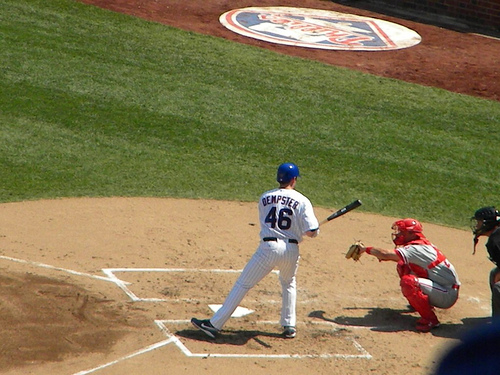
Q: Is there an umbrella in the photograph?
A: No, there are no umbrellas.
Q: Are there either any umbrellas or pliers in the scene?
A: No, there are no umbrellas or pliers.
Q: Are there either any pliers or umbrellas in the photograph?
A: No, there are no umbrellas or pliers.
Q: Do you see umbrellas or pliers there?
A: No, there are no umbrellas or pliers.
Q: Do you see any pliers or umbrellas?
A: No, there are no umbrellas or pliers.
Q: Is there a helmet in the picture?
A: Yes, there is a helmet.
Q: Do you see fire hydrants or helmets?
A: Yes, there is a helmet.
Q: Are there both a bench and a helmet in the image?
A: No, there is a helmet but no benches.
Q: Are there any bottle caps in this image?
A: No, there are no bottle caps.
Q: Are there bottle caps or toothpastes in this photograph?
A: No, there are no bottle caps or toothpastes.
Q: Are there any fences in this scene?
A: No, there are no fences.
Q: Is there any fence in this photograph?
A: No, there are no fences.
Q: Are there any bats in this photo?
A: Yes, there is a bat.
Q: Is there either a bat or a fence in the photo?
A: Yes, there is a bat.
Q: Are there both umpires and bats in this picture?
A: Yes, there are both a bat and an umpire.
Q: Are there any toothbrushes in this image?
A: No, there are no toothbrushes.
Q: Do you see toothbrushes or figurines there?
A: No, there are no toothbrushes or figurines.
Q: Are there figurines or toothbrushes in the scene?
A: No, there are no toothbrushes or figurines.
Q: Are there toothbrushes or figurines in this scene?
A: No, there are no toothbrushes or figurines.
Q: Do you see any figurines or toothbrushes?
A: No, there are no toothbrushes or figurines.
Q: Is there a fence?
A: No, there are no fences.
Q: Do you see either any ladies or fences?
A: No, there are no fences or ladies.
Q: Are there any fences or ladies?
A: No, there are no fences or ladies.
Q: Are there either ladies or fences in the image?
A: No, there are no fences or ladies.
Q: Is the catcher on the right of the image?
A: Yes, the catcher is on the right of the image.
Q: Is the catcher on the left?
A: No, the catcher is on the right of the image.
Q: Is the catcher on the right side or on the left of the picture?
A: The catcher is on the right of the image.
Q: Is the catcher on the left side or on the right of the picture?
A: The catcher is on the right of the image.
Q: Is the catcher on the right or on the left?
A: The catcher is on the right of the image.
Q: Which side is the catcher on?
A: The catcher is on the right of the image.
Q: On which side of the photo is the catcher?
A: The catcher is on the right of the image.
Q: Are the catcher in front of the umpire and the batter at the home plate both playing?
A: Yes, both the catcher and the batter are playing.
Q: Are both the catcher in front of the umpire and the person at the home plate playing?
A: Yes, both the catcher and the batter are playing.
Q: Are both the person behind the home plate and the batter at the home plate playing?
A: Yes, both the catcher and the batter are playing.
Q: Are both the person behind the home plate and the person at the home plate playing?
A: Yes, both the catcher and the batter are playing.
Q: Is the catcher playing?
A: Yes, the catcher is playing.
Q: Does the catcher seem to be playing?
A: Yes, the catcher is playing.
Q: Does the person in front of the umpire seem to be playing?
A: Yes, the catcher is playing.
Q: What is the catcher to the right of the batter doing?
A: The catcher is playing.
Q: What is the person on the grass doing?
A: The catcher is playing.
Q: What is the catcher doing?
A: The catcher is playing.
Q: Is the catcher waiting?
A: No, the catcher is playing.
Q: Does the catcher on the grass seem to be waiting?
A: No, the catcher is playing.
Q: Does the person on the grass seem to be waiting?
A: No, the catcher is playing.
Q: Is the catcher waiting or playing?
A: The catcher is playing.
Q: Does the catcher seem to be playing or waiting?
A: The catcher is playing.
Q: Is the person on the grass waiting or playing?
A: The catcher is playing.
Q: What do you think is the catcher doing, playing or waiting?
A: The catcher is playing.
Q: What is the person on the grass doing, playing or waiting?
A: The catcher is playing.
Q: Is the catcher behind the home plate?
A: Yes, the catcher is behind the home plate.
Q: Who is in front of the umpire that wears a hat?
A: The catcher is in front of the umpire.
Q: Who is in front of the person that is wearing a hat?
A: The catcher is in front of the umpire.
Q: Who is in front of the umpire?
A: The catcher is in front of the umpire.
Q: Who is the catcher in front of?
A: The catcher is in front of the umpire.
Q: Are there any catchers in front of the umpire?
A: Yes, there is a catcher in front of the umpire.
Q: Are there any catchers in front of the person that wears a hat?
A: Yes, there is a catcher in front of the umpire.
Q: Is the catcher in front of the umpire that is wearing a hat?
A: Yes, the catcher is in front of the umpire.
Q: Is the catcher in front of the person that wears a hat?
A: Yes, the catcher is in front of the umpire.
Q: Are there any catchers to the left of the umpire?
A: Yes, there is a catcher to the left of the umpire.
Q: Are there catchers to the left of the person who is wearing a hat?
A: Yes, there is a catcher to the left of the umpire.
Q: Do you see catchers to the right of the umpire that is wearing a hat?
A: No, the catcher is to the left of the umpire.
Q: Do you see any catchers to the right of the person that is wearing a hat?
A: No, the catcher is to the left of the umpire.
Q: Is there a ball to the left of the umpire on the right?
A: No, there is a catcher to the left of the umpire.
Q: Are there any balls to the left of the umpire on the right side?
A: No, there is a catcher to the left of the umpire.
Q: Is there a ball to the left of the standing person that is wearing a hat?
A: No, there is a catcher to the left of the umpire.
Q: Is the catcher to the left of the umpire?
A: Yes, the catcher is to the left of the umpire.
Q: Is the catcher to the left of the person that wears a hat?
A: Yes, the catcher is to the left of the umpire.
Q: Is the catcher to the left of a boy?
A: No, the catcher is to the left of the umpire.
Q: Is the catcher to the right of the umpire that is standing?
A: No, the catcher is to the left of the umpire.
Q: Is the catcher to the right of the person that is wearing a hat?
A: No, the catcher is to the left of the umpire.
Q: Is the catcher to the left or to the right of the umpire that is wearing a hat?
A: The catcher is to the left of the umpire.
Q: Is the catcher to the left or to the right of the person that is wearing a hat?
A: The catcher is to the left of the umpire.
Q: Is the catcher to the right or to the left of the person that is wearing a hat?
A: The catcher is to the left of the umpire.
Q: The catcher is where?
A: The catcher is on the grass.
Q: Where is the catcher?
A: The catcher is on the grass.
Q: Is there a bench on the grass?
A: No, there is a catcher on the grass.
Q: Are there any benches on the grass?
A: No, there is a catcher on the grass.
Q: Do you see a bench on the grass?
A: No, there is a catcher on the grass.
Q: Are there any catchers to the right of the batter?
A: Yes, there is a catcher to the right of the batter.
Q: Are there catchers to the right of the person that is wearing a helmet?
A: Yes, there is a catcher to the right of the batter.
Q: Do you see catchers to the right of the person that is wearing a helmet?
A: Yes, there is a catcher to the right of the batter.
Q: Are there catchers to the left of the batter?
A: No, the catcher is to the right of the batter.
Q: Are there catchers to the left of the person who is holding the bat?
A: No, the catcher is to the right of the batter.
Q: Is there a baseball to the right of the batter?
A: No, there is a catcher to the right of the batter.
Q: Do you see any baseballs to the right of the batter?
A: No, there is a catcher to the right of the batter.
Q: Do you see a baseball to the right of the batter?
A: No, there is a catcher to the right of the batter.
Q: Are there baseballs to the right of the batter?
A: No, there is a catcher to the right of the batter.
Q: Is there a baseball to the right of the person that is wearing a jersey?
A: No, there is a catcher to the right of the batter.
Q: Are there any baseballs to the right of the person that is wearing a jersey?
A: No, there is a catcher to the right of the batter.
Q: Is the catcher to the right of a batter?
A: Yes, the catcher is to the right of a batter.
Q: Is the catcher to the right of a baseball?
A: No, the catcher is to the right of a batter.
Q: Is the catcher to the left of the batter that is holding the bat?
A: No, the catcher is to the right of the batter.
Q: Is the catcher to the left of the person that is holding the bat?
A: No, the catcher is to the right of the batter.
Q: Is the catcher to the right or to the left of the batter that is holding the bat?
A: The catcher is to the right of the batter.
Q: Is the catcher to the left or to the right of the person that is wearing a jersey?
A: The catcher is to the right of the batter.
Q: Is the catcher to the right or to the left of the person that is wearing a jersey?
A: The catcher is to the right of the batter.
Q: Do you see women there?
A: No, there are no women.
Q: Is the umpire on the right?
A: Yes, the umpire is on the right of the image.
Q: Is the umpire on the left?
A: No, the umpire is on the right of the image.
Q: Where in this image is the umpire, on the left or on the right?
A: The umpire is on the right of the image.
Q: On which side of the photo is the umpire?
A: The umpire is on the right of the image.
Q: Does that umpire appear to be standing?
A: Yes, the umpire is standing.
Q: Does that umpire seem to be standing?
A: Yes, the umpire is standing.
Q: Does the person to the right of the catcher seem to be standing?
A: Yes, the umpire is standing.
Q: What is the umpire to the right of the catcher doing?
A: The umpire is standing.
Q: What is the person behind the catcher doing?
A: The umpire is standing.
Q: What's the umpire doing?
A: The umpire is standing.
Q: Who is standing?
A: The umpire is standing.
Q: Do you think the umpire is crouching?
A: No, the umpire is standing.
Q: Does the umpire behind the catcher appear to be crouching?
A: No, the umpire is standing.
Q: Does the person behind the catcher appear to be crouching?
A: No, the umpire is standing.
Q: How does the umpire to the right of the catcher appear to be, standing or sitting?
A: The umpire is standing.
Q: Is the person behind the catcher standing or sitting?
A: The umpire is standing.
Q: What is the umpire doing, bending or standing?
A: The umpire is standing.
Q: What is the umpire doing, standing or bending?
A: The umpire is standing.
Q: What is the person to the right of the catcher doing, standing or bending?
A: The umpire is standing.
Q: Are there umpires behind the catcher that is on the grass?
A: Yes, there is an umpire behind the catcher.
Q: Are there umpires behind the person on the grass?
A: Yes, there is an umpire behind the catcher.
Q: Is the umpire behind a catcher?
A: Yes, the umpire is behind a catcher.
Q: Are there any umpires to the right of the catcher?
A: Yes, there is an umpire to the right of the catcher.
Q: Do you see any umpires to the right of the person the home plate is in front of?
A: Yes, there is an umpire to the right of the catcher.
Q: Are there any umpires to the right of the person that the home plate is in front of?
A: Yes, there is an umpire to the right of the catcher.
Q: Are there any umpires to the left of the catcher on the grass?
A: No, the umpire is to the right of the catcher.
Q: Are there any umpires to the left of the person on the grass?
A: No, the umpire is to the right of the catcher.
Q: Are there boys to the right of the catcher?
A: No, there is an umpire to the right of the catcher.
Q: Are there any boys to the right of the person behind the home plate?
A: No, there is an umpire to the right of the catcher.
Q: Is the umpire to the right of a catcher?
A: Yes, the umpire is to the right of a catcher.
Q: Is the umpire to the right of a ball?
A: No, the umpire is to the right of a catcher.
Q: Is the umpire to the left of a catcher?
A: No, the umpire is to the right of a catcher.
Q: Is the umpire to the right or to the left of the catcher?
A: The umpire is to the right of the catcher.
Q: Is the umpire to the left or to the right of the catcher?
A: The umpire is to the right of the catcher.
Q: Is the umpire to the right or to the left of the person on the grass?
A: The umpire is to the right of the catcher.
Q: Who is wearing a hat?
A: The umpire is wearing a hat.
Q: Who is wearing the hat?
A: The umpire is wearing a hat.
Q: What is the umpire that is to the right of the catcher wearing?
A: The umpire is wearing a hat.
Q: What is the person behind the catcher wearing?
A: The umpire is wearing a hat.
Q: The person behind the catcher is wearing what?
A: The umpire is wearing a hat.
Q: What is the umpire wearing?
A: The umpire is wearing a hat.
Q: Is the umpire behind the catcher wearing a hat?
A: Yes, the umpire is wearing a hat.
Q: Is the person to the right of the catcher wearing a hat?
A: Yes, the umpire is wearing a hat.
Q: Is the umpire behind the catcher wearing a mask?
A: No, the umpire is wearing a hat.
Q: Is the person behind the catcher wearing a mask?
A: No, the umpire is wearing a hat.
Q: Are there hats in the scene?
A: Yes, there is a hat.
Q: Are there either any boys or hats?
A: Yes, there is a hat.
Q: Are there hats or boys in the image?
A: Yes, there is a hat.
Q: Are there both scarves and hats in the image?
A: No, there is a hat but no scarves.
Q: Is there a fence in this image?
A: No, there are no fences.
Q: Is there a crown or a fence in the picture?
A: No, there are no fences or crowns.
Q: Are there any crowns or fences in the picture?
A: No, there are no fences or crowns.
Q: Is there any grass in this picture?
A: Yes, there is grass.